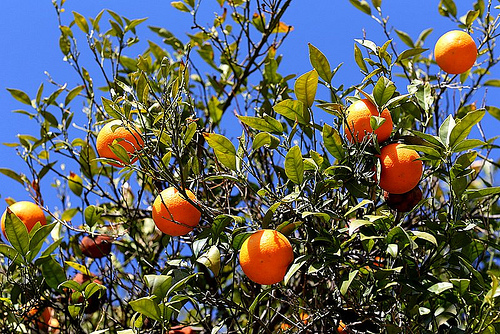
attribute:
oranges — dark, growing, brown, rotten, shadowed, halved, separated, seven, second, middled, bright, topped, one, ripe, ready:
[1, 28, 476, 291]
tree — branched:
[1, 2, 499, 326]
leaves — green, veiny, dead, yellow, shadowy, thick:
[1, 1, 499, 321]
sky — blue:
[2, 1, 458, 334]